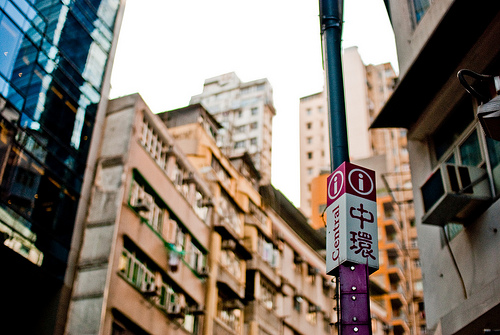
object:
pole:
[318, 3, 379, 335]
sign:
[327, 161, 378, 270]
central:
[328, 206, 344, 264]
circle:
[348, 166, 374, 196]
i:
[356, 173, 367, 189]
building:
[2, 3, 125, 333]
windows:
[8, 15, 77, 127]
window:
[131, 263, 143, 283]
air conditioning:
[422, 165, 496, 225]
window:
[422, 111, 492, 218]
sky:
[108, 1, 415, 213]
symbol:
[327, 172, 346, 197]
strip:
[124, 184, 216, 285]